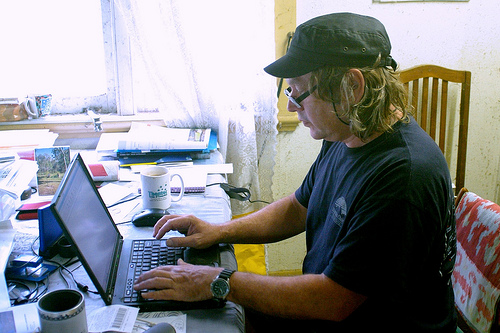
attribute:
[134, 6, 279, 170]
curtain — sheer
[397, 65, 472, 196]
chair — wooden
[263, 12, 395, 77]
cap — black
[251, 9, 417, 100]
cap — black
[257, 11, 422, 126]
hair — blond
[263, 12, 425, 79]
cap — black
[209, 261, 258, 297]
watch — silver and grey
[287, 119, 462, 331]
t-shirt — black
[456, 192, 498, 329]
blanket — red, grey, patterned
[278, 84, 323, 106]
reading glasses — black framed